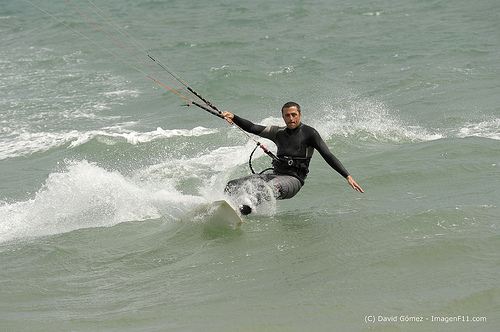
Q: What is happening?
A: Kite surfing.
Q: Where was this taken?
A: The ocean.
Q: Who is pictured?
A: A kite surfer.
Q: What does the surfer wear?
A: A wet suit.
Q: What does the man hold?
A: The lanyard to the kite.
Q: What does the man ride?
A: Surfboard.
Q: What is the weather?
A: Sunny.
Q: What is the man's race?
A: Caucasian.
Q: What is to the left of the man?
A: Cresting waves.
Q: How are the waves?
A: Foamy and white.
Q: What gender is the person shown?
A: Male.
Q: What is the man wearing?
A: Wetsuit.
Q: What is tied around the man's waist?
A: Kite string.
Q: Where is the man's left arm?
A: Straight and aimed toward the water.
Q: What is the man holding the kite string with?
A: Right.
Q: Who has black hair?
A: Surfer.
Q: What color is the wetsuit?
A: Black.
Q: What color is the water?
A: Blue.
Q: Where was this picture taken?
A: On the ocean.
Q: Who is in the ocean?
A: A man.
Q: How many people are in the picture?
A: One.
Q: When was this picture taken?
A: During the day.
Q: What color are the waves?
A: White.